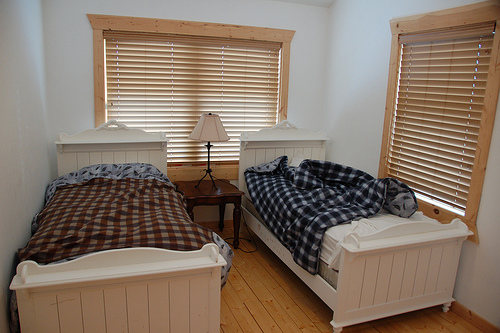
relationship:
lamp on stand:
[187, 113, 230, 194] [173, 176, 249, 251]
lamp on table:
[187, 113, 239, 183] [179, 157, 251, 216]